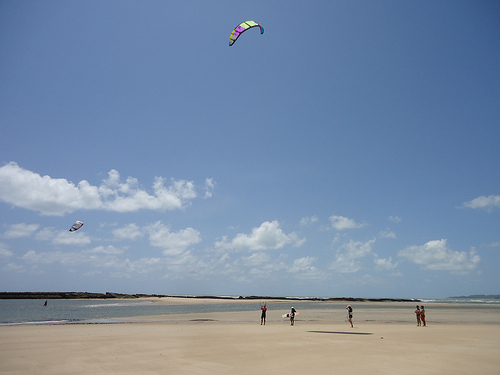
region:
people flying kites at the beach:
[36, 13, 464, 366]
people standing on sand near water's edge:
[150, 280, 470, 351]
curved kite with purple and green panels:
[201, 7, 288, 52]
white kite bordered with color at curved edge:
[56, 210, 101, 246]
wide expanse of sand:
[35, 280, 470, 365]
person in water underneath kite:
[25, 185, 110, 321]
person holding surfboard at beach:
[271, 300, 308, 345]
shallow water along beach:
[25, 287, 405, 322]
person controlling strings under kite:
[220, 12, 280, 349]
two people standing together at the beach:
[392, 280, 453, 350]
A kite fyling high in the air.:
[214, 12, 279, 52]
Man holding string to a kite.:
[255, 296, 276, 330]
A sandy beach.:
[31, 311, 486, 368]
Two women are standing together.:
[407, 299, 434, 332]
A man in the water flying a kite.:
[29, 215, 99, 314]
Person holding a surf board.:
[276, 301, 313, 336]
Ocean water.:
[0, 284, 259, 331]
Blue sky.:
[4, 55, 476, 155]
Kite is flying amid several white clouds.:
[22, 207, 468, 285]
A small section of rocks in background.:
[1, 286, 153, 303]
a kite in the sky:
[219, 19, 291, 71]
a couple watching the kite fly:
[404, 306, 439, 336]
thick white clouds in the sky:
[13, 157, 163, 210]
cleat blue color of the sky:
[255, 141, 384, 199]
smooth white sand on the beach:
[147, 331, 243, 373]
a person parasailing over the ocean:
[39, 201, 79, 323]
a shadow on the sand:
[308, 323, 370, 339]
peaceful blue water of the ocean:
[59, 302, 91, 319]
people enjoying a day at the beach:
[47, 24, 435, 345]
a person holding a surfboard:
[284, 301, 315, 331]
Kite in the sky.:
[210, 2, 315, 79]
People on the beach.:
[212, 262, 474, 367]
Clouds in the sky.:
[36, 170, 416, 342]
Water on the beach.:
[27, 273, 149, 360]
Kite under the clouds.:
[57, 199, 115, 257]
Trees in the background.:
[66, 281, 230, 313]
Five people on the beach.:
[240, 280, 437, 342]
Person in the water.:
[30, 292, 78, 316]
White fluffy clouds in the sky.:
[117, 172, 266, 239]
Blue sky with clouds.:
[226, 145, 435, 327]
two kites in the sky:
[14, 20, 283, 255]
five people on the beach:
[191, 284, 455, 333]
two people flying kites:
[228, 289, 471, 350]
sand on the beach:
[17, 312, 452, 374]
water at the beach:
[10, 277, 392, 317]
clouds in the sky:
[13, 147, 495, 300]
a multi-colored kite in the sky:
[215, 12, 330, 49]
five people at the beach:
[239, 280, 470, 354]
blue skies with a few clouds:
[1, 1, 494, 316]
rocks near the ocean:
[9, 275, 388, 311]